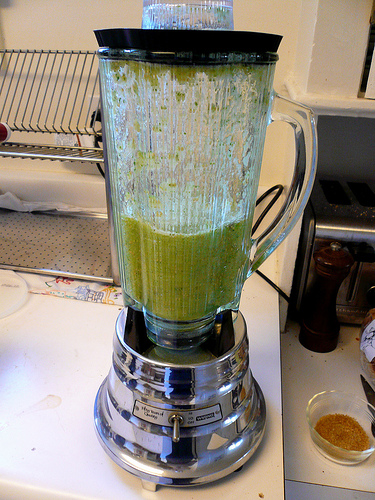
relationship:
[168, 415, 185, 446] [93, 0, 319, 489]
button on blender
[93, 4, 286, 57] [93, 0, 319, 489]
lid of blender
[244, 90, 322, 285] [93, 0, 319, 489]
handle of blender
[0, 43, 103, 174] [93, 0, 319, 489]
grate behind blender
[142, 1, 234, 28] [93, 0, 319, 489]
coveredopening on blender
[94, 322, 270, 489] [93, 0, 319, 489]
base of blender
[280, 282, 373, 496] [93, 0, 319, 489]
table next to blender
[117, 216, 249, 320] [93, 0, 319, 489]
green stuff inside blender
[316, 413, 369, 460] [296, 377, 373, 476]
stuff in dish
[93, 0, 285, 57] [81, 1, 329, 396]
lid of blender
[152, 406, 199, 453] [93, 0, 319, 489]
button on blender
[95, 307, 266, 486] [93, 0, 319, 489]
reflections on blender